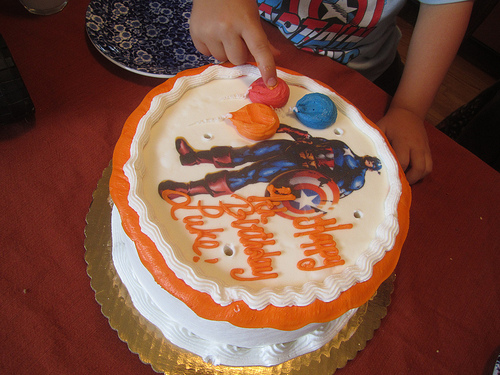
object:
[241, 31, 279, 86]
finger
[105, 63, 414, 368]
cake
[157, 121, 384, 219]
action hero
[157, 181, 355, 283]
writing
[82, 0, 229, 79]
plate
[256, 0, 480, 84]
shirt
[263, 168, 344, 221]
battle shield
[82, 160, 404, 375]
platter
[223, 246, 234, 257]
hole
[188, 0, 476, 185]
child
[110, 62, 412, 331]
border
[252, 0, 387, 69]
captain america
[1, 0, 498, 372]
table cloth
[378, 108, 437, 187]
hand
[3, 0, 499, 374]
table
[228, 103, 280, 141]
ball of frosting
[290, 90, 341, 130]
ball of frosting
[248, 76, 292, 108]
ball of frosting